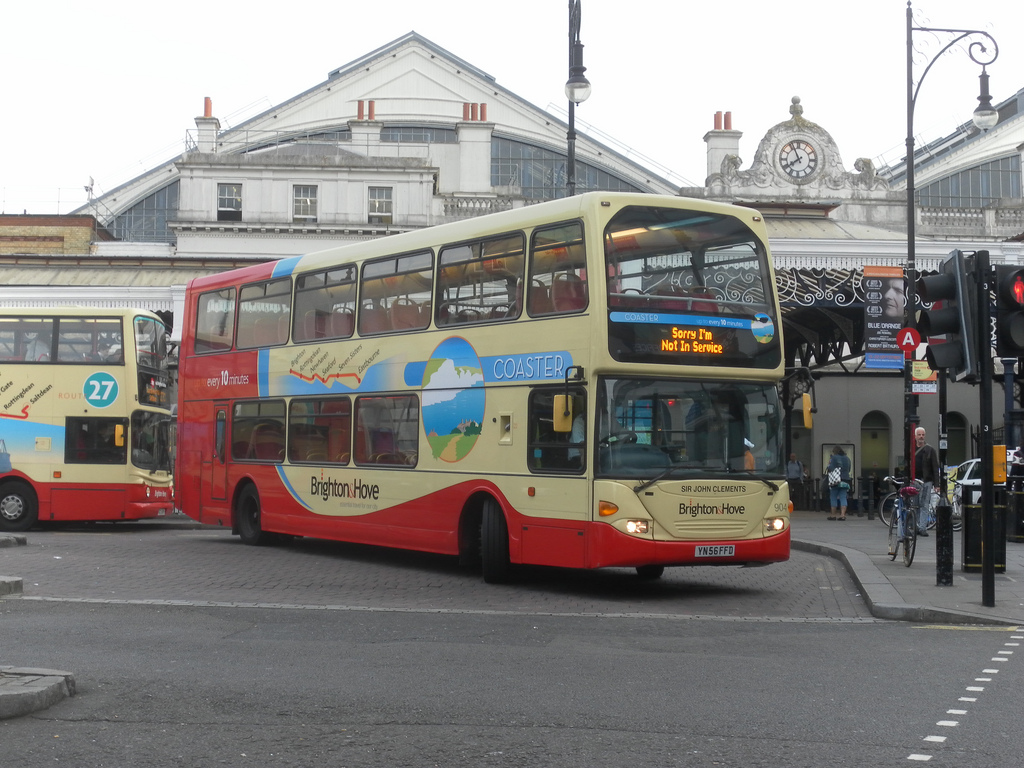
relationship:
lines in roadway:
[918, 627, 1016, 742] [0, 518, 1016, 768]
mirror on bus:
[516, 353, 622, 487] [215, 229, 743, 580]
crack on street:
[155, 675, 631, 747] [116, 571, 771, 760]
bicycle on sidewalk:
[860, 472, 949, 591] [855, 445, 979, 692]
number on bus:
[646, 276, 765, 357] [397, 239, 747, 643]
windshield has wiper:
[568, 361, 854, 513] [643, 454, 806, 494]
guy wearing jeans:
[870, 422, 968, 593] [892, 471, 931, 554]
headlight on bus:
[609, 497, 832, 552] [161, 215, 775, 596]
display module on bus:
[626, 286, 793, 375] [202, 236, 749, 504]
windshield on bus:
[613, 214, 817, 335] [166, 262, 778, 533]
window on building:
[188, 130, 292, 269] [69, 24, 917, 683]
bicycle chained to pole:
[882, 470, 928, 568] [819, 1, 953, 593]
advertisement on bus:
[389, 284, 597, 580] [147, 173, 861, 666]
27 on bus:
[69, 355, 147, 444] [39, 240, 251, 575]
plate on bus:
[617, 456, 840, 616] [172, 191, 816, 635]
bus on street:
[169, 182, 794, 588] [82, 558, 759, 708]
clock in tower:
[784, 135, 830, 181] [725, 55, 907, 529]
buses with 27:
[0, 294, 183, 528] [80, 367, 119, 406]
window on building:
[315, 124, 357, 148] [65, 20, 696, 247]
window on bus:
[225, 387, 286, 465] [169, 182, 794, 588]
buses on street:
[4, 187, 797, 613] [10, 505, 1015, 765]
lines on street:
[924, 610, 1020, 738] [286, 541, 1013, 758]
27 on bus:
[80, 367, 119, 406] [6, 285, 184, 545]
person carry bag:
[810, 438, 858, 519] [821, 456, 847, 489]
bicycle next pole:
[882, 470, 928, 568] [896, 10, 925, 575]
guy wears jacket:
[909, 424, 941, 537] [910, 445, 950, 489]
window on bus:
[515, 208, 598, 330] [161, 158, 842, 643]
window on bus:
[443, 219, 526, 347] [147, 173, 861, 666]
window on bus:
[175, 167, 815, 576] [353, 247, 440, 341]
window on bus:
[230, 273, 302, 356] [151, 170, 821, 609]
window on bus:
[234, 275, 291, 358] [102, 180, 900, 621]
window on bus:
[189, 301, 239, 358] [152, 184, 865, 591]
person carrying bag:
[819, 438, 855, 522] [816, 463, 849, 492]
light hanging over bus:
[561, 16, 592, 110] [196, 197, 812, 565]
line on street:
[907, 675, 970, 764] [719, 651, 778, 757]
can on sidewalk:
[958, 508, 987, 571] [917, 560, 948, 621]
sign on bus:
[610, 325, 755, 360] [161, 215, 775, 596]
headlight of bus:
[622, 518, 649, 535] [174, 195, 790, 610]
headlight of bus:
[622, 518, 649, 535] [161, 215, 775, 596]